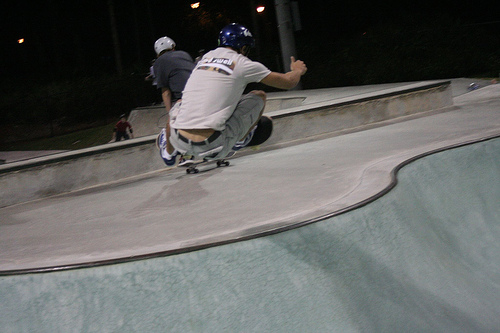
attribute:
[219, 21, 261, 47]
helmet — white, blue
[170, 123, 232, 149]
belt — black, brown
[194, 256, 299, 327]
pavement — gray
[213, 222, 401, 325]
ramp — grey, gray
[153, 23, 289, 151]
man — practicing, skateboarder, above, skating, wearing, doing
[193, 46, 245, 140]
shirt — white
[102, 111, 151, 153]
men — skating, sitting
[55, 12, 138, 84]
view — beautiful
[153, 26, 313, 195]
person — wearing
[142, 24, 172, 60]
cap — white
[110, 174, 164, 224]
road — curved, clean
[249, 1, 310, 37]
pillar — small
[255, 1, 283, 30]
light — bright, small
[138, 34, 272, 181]
skateboarders — infront, performing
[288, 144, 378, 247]
surface — grey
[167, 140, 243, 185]
rider — low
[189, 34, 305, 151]
skateboarder — approaching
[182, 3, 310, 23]
lights — shining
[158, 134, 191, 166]
foot — sticking otu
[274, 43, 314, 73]
thumbs — up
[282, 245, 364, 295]
jump — blue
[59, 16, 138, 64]
sky — black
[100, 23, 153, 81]
pole — steel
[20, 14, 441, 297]
photo — taken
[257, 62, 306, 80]
arm — outstretched